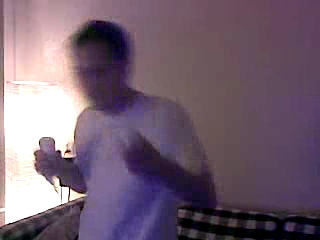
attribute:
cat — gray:
[48, 204, 84, 239]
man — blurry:
[33, 18, 223, 240]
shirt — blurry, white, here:
[74, 92, 207, 239]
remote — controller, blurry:
[34, 135, 58, 179]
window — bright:
[4, 3, 64, 91]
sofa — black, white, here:
[1, 196, 318, 237]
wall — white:
[224, 5, 317, 206]